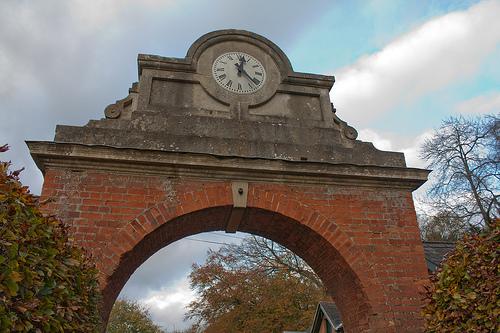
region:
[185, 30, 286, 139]
whie clock with black hands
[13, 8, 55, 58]
white clouds in blue sky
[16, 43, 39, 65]
white clouds in blue sky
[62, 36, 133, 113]
white clouds in blue sky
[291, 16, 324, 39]
white clouds in blue sky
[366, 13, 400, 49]
white clouds in blue sky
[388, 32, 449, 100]
white clouds in blue sky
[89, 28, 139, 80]
white clouds in blue sky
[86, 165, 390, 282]
red brick arch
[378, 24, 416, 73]
white clouds in blue sky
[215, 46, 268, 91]
The clock on the top of the structure.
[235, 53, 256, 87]
The hands on the clock.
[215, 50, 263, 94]
The Roman numerals of the clock.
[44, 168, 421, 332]
The red brick of the structure.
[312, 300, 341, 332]
The pointed roof in the middle.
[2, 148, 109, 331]
The bushes on the left.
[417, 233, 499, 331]
The bush on the right.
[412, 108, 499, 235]
The tree on the right.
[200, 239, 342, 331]
The tree in the middle.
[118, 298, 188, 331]
The trees in the distance.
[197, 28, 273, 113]
clock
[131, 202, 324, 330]
arch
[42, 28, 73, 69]
white clouds in blue sky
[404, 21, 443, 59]
white clouds in blue sky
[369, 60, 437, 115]
white clouds in blue sky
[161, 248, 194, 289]
white clouds in blue sky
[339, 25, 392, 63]
white clouds in blue sky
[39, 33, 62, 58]
white clouds in blue sky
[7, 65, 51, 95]
white clouds in blue sky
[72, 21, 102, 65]
white clouds in blue sky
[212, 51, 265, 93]
a large black and white clock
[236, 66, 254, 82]
a clock's minute hand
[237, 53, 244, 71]
a clock's hour hand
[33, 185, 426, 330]
a red brick archway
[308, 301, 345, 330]
the dormer of a house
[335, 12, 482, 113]
a white cloud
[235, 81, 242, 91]
roman numeral VI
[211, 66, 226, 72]
roman numeral 9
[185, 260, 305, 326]
a portion of a leafy tree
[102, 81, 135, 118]
cement scrollwork detail on archway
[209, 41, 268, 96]
white and black clock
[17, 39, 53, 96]
white clouds in blue sky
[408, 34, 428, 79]
white clouds in blue sky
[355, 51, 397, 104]
white clouds in blue sky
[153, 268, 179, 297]
white clouds in blue sky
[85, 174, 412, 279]
brick arch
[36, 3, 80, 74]
white clouds in blue sky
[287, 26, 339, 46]
white clouds in blue sky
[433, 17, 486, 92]
white clouds in blue sky